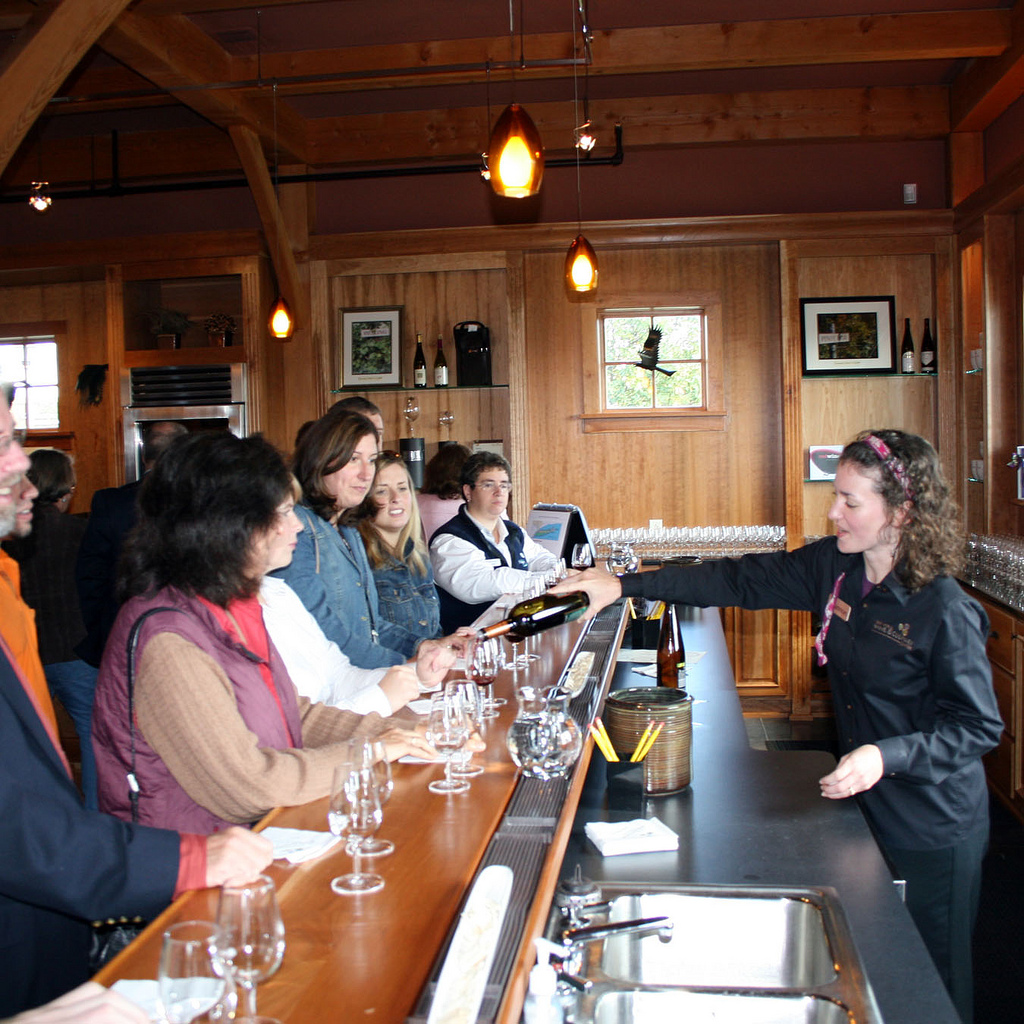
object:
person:
[544, 429, 1007, 1024]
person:
[257, 467, 450, 719]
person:
[266, 411, 475, 670]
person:
[358, 451, 444, 640]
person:
[429, 450, 583, 636]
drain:
[554, 863, 603, 908]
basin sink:
[559, 881, 883, 1022]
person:
[89, 427, 438, 840]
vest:
[90, 585, 303, 836]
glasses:
[327, 783, 385, 897]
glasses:
[348, 736, 393, 806]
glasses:
[425, 688, 470, 795]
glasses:
[206, 878, 286, 1024]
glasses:
[159, 919, 234, 1024]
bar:
[83, 557, 642, 1024]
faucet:
[563, 916, 669, 937]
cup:
[607, 752, 649, 813]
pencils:
[587, 716, 665, 762]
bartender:
[521, 605, 966, 1024]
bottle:
[477, 590, 590, 642]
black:
[406, 597, 965, 1024]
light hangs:
[564, 234, 599, 303]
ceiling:
[0, 0, 1021, 192]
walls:
[309, 209, 949, 694]